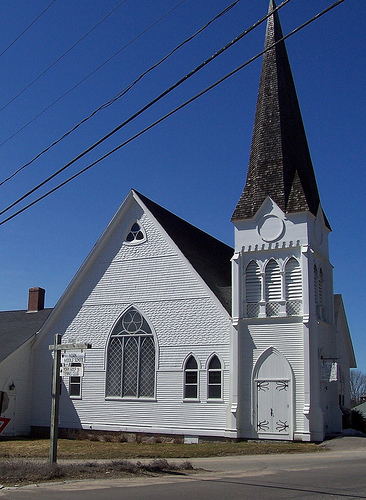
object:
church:
[0, 0, 357, 447]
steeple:
[229, 2, 356, 444]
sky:
[1, 0, 365, 403]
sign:
[59, 352, 85, 376]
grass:
[0, 433, 332, 488]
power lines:
[0, 0, 52, 55]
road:
[0, 436, 365, 500]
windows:
[207, 355, 222, 398]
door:
[257, 381, 289, 434]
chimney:
[26, 286, 47, 314]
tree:
[349, 367, 364, 407]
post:
[49, 333, 62, 466]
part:
[292, 465, 322, 488]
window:
[184, 355, 198, 398]